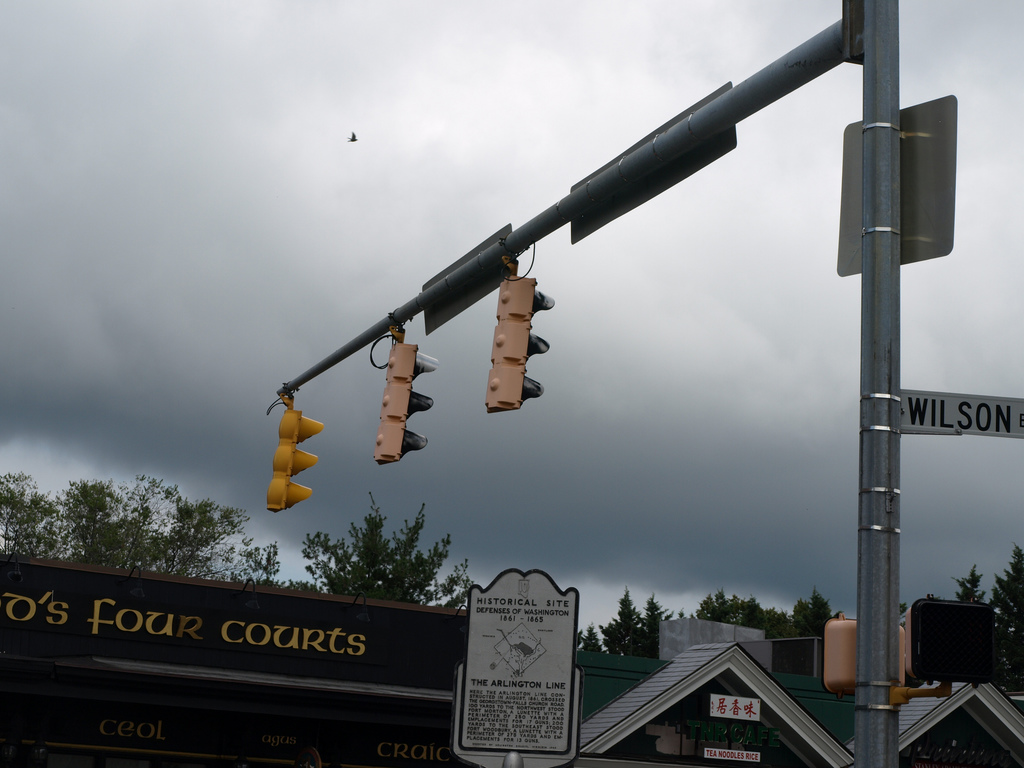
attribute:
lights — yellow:
[266, 397, 330, 515]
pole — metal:
[841, 37, 932, 293]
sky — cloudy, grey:
[117, 61, 301, 245]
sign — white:
[912, 368, 1019, 466]